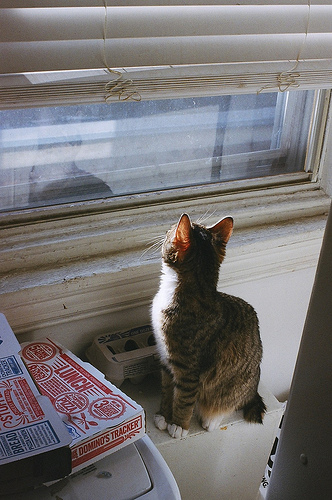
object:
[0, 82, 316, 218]
window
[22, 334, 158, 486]
box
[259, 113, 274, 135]
ground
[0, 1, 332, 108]
blind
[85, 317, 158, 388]
part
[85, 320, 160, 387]
carton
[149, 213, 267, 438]
cat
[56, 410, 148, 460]
printed message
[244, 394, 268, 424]
tail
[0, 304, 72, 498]
box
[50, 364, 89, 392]
word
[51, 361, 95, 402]
lunch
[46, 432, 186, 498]
trash receptacle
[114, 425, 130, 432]
part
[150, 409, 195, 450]
feet